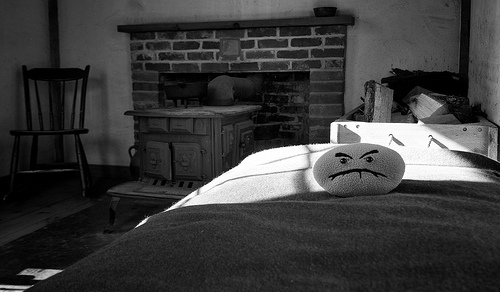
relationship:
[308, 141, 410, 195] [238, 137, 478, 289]
pillow on bed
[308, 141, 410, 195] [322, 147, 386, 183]
pillow has design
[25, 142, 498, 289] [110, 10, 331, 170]
bed near fireplace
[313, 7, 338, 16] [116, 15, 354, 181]
bowl above fireplace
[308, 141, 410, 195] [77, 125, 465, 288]
pillow on bed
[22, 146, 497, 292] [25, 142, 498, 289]
sheets on bed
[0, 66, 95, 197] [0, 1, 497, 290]
chair in room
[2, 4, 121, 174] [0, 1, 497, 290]
corner in room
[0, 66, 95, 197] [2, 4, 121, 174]
chair in corner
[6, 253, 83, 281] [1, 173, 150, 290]
sun light on floor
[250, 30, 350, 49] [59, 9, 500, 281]
brick inside room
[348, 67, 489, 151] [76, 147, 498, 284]
firewood next to bed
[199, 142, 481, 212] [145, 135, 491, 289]
sunlight on bed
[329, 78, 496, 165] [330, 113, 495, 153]
sunlight on box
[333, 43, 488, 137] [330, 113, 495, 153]
firewood in box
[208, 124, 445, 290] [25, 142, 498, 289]
sheets on bed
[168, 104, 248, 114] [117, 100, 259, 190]
ash on wood burner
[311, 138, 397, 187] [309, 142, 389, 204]
face on pillow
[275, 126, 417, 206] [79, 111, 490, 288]
pillow on bed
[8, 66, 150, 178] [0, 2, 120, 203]
chair next to corner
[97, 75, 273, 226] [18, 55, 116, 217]
stove next to chair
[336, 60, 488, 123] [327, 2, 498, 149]
firewood in corner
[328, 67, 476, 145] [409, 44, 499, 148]
logs in corner